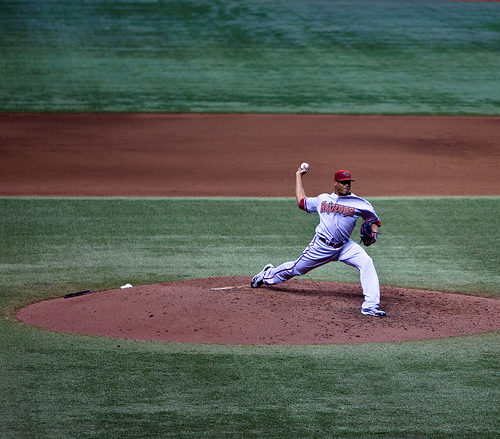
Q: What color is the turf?
A: Green.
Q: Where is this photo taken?
A: On a baseball field.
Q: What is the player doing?
A: Preparing to throw a ball.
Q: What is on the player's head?
A: A cap.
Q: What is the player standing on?
A: A mound.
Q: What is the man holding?
A: A ball and mitt.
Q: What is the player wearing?
A: A uniform.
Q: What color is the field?
A: Green and brown.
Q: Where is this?
A: A baseball field.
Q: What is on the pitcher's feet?
A: Cleats.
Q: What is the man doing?
A: Pitching a ball.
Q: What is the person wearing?
A: A baseball uniform.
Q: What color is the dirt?
A: Brown.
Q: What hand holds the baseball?
A: The right hand.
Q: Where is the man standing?
A: On the pitcher's mound.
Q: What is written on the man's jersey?
A: Arizona.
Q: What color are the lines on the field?
A: White.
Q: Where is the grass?
A: Around the pitchers mound.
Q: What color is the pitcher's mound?
A: Brown.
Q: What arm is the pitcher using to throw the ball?
A: Right.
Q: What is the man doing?
A: Throwing a baseball.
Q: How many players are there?
A: One.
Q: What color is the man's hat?
A: Red.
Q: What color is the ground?
A: Green and brown.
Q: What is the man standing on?
A: Pitcher's mound.